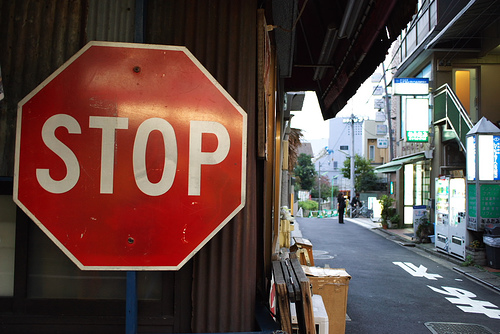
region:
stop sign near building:
[22, 54, 229, 279]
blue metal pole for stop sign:
[98, 276, 167, 331]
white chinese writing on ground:
[396, 252, 462, 331]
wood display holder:
[260, 256, 334, 332]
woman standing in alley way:
[326, 197, 358, 218]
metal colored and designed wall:
[158, 10, 304, 60]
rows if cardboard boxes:
[296, 215, 331, 312]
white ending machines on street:
[424, 181, 470, 245]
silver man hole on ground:
[418, 312, 455, 331]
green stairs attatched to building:
[443, 86, 483, 129]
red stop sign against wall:
[0, 31, 257, 284]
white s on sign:
[30, 109, 92, 194]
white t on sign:
[88, 113, 128, 210]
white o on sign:
[126, 118, 182, 205]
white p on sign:
[184, 118, 230, 198]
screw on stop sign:
[115, 55, 151, 80]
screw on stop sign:
[117, 230, 146, 249]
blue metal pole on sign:
[117, 272, 144, 332]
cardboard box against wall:
[311, 264, 363, 326]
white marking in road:
[379, 248, 438, 280]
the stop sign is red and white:
[8, 32, 241, 309]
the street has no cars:
[307, 218, 469, 323]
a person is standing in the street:
[324, 181, 357, 233]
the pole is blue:
[95, 268, 153, 331]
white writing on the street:
[383, 238, 495, 327]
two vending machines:
[415, 150, 469, 265]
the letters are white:
[39, 95, 221, 204]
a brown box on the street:
[276, 254, 355, 319]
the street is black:
[328, 219, 431, 318]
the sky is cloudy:
[292, 105, 365, 127]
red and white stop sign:
[2, 32, 252, 291]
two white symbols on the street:
[390, 248, 496, 329]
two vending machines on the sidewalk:
[433, 172, 468, 262]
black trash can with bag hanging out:
[480, 216, 496, 267]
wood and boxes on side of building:
[273, 253, 354, 330]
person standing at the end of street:
[331, 190, 351, 225]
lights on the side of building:
[310, 0, 360, 85]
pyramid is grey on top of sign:
[465, 115, 498, 135]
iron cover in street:
[420, 313, 491, 330]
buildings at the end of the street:
[297, 114, 388, 251]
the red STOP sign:
[15, 37, 246, 274]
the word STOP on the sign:
[35, 105, 227, 197]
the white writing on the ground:
[391, 253, 466, 320]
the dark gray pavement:
[335, 228, 382, 278]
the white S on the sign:
[33, 112, 84, 193]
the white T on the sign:
[85, 110, 130, 197]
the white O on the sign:
[133, 113, 176, 195]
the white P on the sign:
[185, 117, 232, 207]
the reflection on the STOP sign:
[117, 94, 234, 129]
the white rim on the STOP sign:
[87, 36, 185, 56]